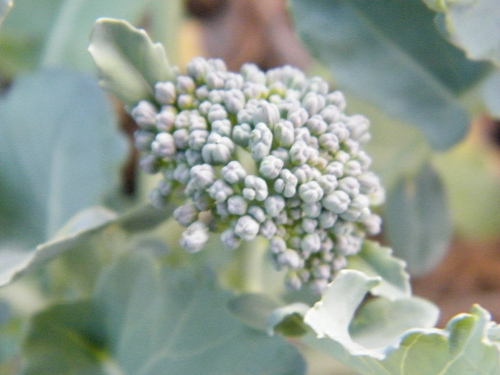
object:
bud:
[219, 158, 248, 185]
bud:
[240, 173, 271, 204]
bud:
[200, 130, 238, 166]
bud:
[189, 161, 216, 192]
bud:
[259, 154, 287, 179]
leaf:
[285, 0, 499, 157]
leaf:
[380, 306, 498, 373]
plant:
[130, 55, 388, 290]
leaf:
[87, 15, 184, 119]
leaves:
[0, 175, 176, 291]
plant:
[305, 269, 439, 360]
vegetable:
[96, 17, 386, 292]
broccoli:
[129, 55, 384, 295]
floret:
[246, 124, 272, 158]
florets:
[272, 117, 295, 148]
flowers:
[470, 108, 499, 172]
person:
[187, 3, 233, 22]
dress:
[180, 19, 205, 73]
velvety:
[150, 299, 220, 324]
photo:
[2, 2, 499, 374]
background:
[186, 2, 314, 73]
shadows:
[113, 204, 170, 235]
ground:
[371, 224, 498, 330]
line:
[101, 24, 158, 105]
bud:
[186, 57, 213, 85]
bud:
[225, 87, 244, 113]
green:
[3, 2, 70, 59]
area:
[186, 3, 310, 72]